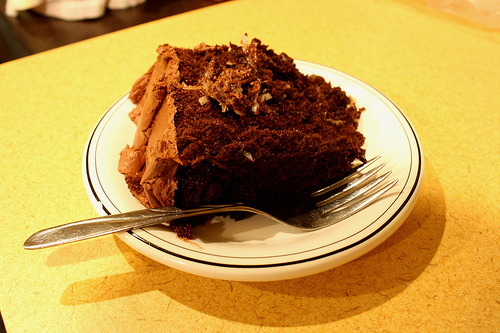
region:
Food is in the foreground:
[81, 36, 383, 236]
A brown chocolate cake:
[105, 35, 375, 230]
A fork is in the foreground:
[5, 150, 395, 275]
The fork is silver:
[15, 145, 395, 265]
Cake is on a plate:
[60, 25, 451, 285]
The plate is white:
[67, 52, 437, 287]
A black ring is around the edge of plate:
[55, 60, 447, 285]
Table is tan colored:
[0, 17, 496, 327]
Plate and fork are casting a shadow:
[40, 152, 473, 328]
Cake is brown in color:
[121, 37, 378, 217]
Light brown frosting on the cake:
[113, 39, 199, 228]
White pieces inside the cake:
[195, 90, 264, 167]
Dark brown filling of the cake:
[167, 44, 367, 232]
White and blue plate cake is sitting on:
[82, 54, 432, 294]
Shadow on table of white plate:
[112, 153, 461, 329]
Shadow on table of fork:
[52, 249, 172, 320]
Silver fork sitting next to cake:
[20, 154, 414, 262]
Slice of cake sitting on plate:
[105, 35, 384, 236]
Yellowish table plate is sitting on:
[3, 1, 496, 329]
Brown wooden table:
[0, 2, 205, 62]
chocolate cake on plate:
[180, 41, 371, 224]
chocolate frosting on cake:
[116, 48, 180, 212]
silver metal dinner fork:
[9, 168, 399, 241]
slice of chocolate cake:
[118, 41, 360, 222]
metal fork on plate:
[19, 159, 406, 246]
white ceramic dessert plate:
[72, 60, 423, 276]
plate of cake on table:
[82, 43, 418, 273]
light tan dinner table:
[5, 5, 497, 330]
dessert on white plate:
[130, 43, 360, 214]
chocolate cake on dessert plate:
[133, 45, 350, 219]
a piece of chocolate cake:
[114, 30, 374, 230]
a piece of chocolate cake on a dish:
[77, 36, 434, 290]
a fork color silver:
[16, 155, 405, 270]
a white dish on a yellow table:
[76, 45, 434, 291]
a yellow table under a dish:
[2, 9, 498, 326]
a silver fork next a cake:
[14, 33, 404, 258]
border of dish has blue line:
[76, 46, 433, 290]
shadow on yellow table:
[65, 277, 481, 330]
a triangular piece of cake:
[113, 31, 371, 228]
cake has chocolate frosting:
[110, 26, 375, 234]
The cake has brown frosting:
[128, 52, 364, 222]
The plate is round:
[78, 52, 428, 268]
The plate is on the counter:
[58, 48, 449, 301]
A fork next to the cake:
[20, 55, 404, 261]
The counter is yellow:
[13, 56, 465, 318]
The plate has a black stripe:
[82, 60, 429, 275]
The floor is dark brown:
[11, 11, 146, 60]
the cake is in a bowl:
[64, 27, 436, 280]